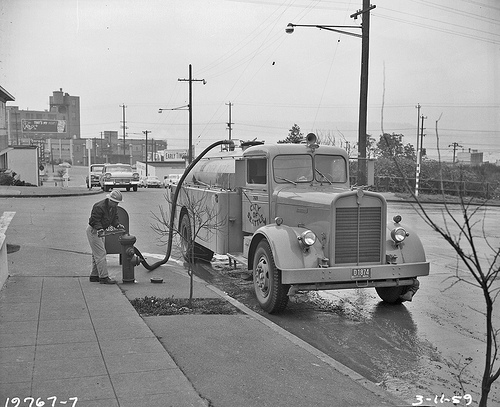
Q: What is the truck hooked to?
A: The hydrant.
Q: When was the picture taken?
A: 3/11/1959.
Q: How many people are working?
A: One.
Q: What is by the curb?
A: Tree.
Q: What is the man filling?
A: The hydrant.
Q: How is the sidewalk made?
A: Paved.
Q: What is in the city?
A: Buildings.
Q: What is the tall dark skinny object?
A: Pole.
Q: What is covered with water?
A: The road.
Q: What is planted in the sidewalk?
A: Tree.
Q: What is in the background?
A: Buildings.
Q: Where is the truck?
A: Parked along the street.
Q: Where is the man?
A: Working with the fire hydrant.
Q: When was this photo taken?
A: 3-11-59.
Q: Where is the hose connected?
A: From the truck to the hydrant.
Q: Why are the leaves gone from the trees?
A: It is winter.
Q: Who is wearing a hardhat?
A: The man near the fire hydrant.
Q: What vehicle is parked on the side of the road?
A: An old fire truck.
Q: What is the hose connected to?
A: A hydrant.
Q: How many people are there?
A: One.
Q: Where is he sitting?
A: Sidewalk.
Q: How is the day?
A: Cloudy.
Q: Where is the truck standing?
A: On road.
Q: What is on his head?
A: Hat.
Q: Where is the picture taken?
A: On the corner of a fire hydrant.